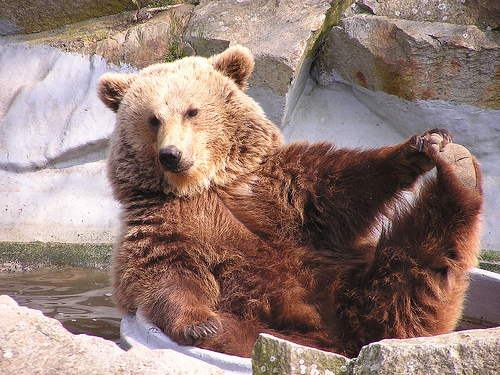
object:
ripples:
[60, 312, 120, 328]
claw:
[189, 329, 199, 339]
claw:
[195, 325, 207, 336]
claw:
[197, 323, 213, 335]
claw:
[207, 322, 218, 331]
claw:
[206, 324, 217, 334]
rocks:
[0, 0, 333, 88]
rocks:
[0, 102, 109, 234]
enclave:
[3, 5, 491, 363]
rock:
[250, 332, 354, 374]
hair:
[148, 68, 196, 107]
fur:
[148, 221, 257, 296]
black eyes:
[187, 108, 198, 117]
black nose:
[159, 145, 183, 168]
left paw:
[406, 127, 454, 163]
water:
[2, 263, 124, 338]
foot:
[426, 132, 483, 207]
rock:
[307, 0, 500, 155]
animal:
[95, 43, 484, 359]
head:
[95, 44, 283, 197]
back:
[105, 220, 263, 365]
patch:
[321, 256, 355, 304]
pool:
[1, 226, 493, 374]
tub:
[117, 267, 500, 375]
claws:
[417, 130, 453, 154]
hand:
[165, 309, 224, 347]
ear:
[95, 72, 135, 114]